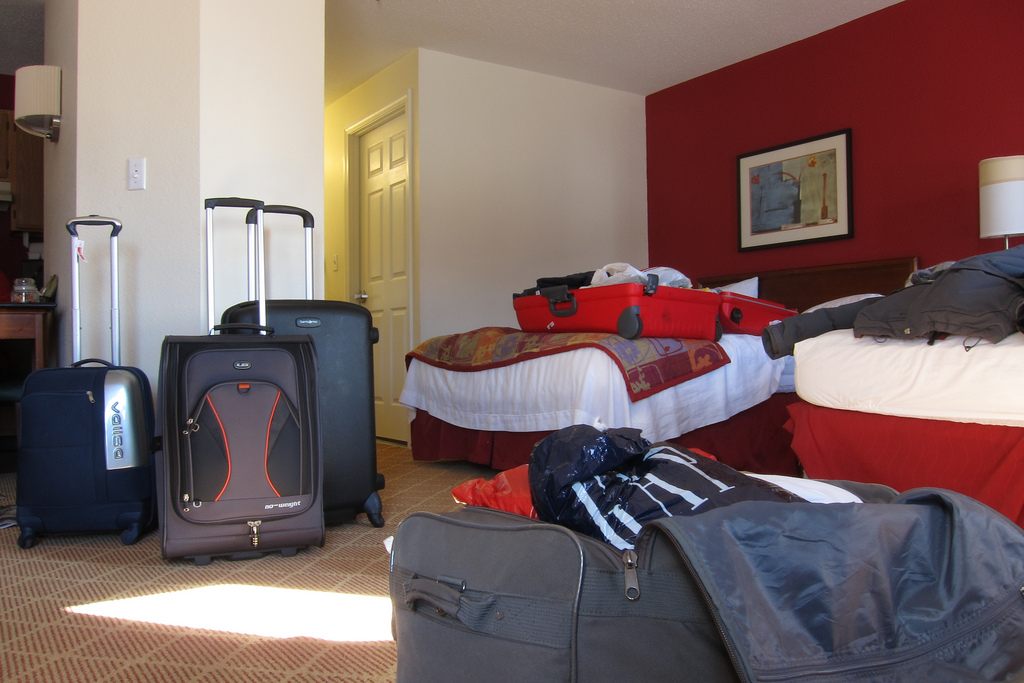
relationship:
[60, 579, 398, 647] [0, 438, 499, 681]
light on floor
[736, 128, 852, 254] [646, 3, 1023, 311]
painting on wall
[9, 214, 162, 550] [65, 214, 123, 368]
suitcase with handle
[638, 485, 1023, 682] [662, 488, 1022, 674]
flap showing bags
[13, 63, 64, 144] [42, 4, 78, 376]
fixture attached to wall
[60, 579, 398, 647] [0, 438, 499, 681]
light across floor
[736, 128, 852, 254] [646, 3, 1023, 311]
painting attached to wall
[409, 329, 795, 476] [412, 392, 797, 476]
bed with skirt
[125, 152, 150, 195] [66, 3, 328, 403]
switch on wall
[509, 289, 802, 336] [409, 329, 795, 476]
suitcase on bed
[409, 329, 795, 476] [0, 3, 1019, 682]
bed in room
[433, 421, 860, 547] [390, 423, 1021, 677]
clothes in bag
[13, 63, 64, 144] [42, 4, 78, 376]
fixture on wall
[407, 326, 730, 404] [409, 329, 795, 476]
blanket on bed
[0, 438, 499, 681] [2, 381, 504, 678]
floor on floor